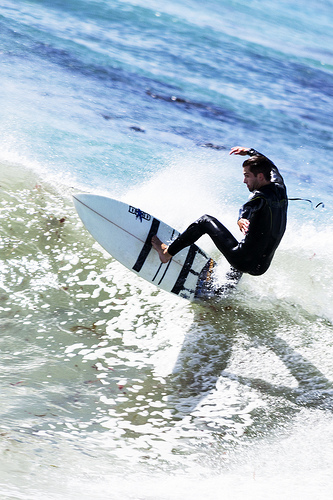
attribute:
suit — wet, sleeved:
[207, 173, 301, 270]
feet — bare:
[155, 231, 248, 278]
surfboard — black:
[81, 200, 222, 293]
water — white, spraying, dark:
[110, 271, 238, 441]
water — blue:
[99, 42, 290, 110]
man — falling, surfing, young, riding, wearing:
[177, 72, 332, 275]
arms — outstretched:
[207, 119, 269, 160]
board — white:
[68, 183, 156, 247]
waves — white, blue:
[26, 159, 136, 300]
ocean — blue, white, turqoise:
[81, 20, 327, 140]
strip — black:
[93, 209, 181, 264]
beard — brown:
[227, 180, 284, 203]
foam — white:
[109, 155, 221, 210]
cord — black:
[173, 287, 242, 339]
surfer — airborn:
[81, 148, 320, 373]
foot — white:
[146, 249, 197, 292]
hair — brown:
[239, 151, 282, 172]